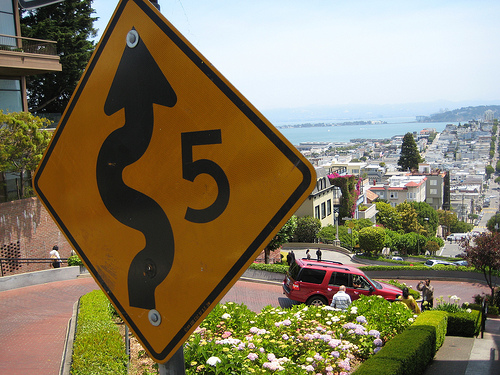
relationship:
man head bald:
[338, 285, 350, 296] [336, 282, 350, 293]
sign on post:
[30, 0, 333, 367] [142, 342, 190, 374]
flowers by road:
[208, 304, 398, 372] [0, 278, 499, 375]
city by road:
[298, 126, 498, 258] [0, 278, 499, 375]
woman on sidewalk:
[43, 241, 61, 267] [4, 265, 90, 287]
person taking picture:
[416, 275, 439, 313] [416, 278, 427, 285]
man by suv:
[338, 285, 350, 296] [279, 254, 403, 311]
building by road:
[1, 1, 60, 200] [0, 278, 499, 375]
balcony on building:
[1, 26, 72, 76] [1, 1, 60, 200]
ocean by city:
[283, 123, 471, 149] [298, 126, 498, 258]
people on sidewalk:
[303, 245, 323, 261] [276, 246, 348, 264]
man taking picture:
[338, 285, 350, 296] [416, 278, 427, 285]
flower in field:
[207, 355, 223, 370] [208, 304, 398, 372]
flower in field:
[218, 337, 244, 349] [208, 304, 398, 372]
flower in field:
[250, 325, 267, 339] [208, 304, 398, 372]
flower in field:
[263, 352, 284, 369] [208, 304, 398, 372]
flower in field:
[346, 322, 366, 336] [208, 304, 398, 372]